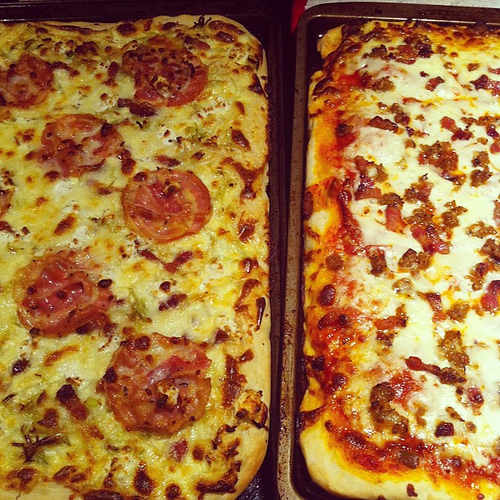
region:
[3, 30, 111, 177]
pizza with meat toppings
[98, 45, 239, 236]
pizza with meat toppings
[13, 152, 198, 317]
pizza with meat toppings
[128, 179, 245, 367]
pizza with meat toppings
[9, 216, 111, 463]
pizza with meat toppings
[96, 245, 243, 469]
pizza with meat toppings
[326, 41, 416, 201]
pizza with meat toppings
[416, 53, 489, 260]
pizza with meat toppings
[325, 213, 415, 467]
pizza with meat toppings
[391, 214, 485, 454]
pizza with meat toppings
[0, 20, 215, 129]
cheese and pepperoni on pizza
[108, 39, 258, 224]
cheese and pepperoni on pizza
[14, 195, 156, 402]
cheese and pepperoni on pizza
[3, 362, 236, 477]
cheese and pepperoni on pizza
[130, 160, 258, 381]
cheese and pepperoni on pizza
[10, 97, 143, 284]
cheese and pepperoni on pizza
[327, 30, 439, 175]
cheese and sausage on pizza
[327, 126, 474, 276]
cheese and sausage on pizza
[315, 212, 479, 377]
cheese and sausage on pizza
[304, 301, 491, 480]
cheese and sausage on pizza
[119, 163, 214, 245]
a piece of ham on the pizza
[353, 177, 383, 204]
a piece of sausage on the pizza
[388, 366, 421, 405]
a piece of bacon on the pizza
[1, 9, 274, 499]
a pizza with ham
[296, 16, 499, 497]
a pizza with sausage and bacon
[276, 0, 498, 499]
a metal pan under the pizza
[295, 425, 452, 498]
a brown crust on the pizza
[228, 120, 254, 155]
a brown spot on the pizza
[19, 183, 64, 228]
yellow cheese on the pizza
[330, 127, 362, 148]
a spot of tomato sauce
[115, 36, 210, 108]
Top middle pepperoni.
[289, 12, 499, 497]
Pizza on the right.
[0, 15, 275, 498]
A pepperoni pizza on the left.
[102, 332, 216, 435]
Bottom middle piece of pepperoni.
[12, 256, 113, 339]
Left piece of pepperoni on the bottom.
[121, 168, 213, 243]
A middle piece of pepperoni on the right.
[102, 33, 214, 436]
Three pieces of pepperoni coming down the inside edge.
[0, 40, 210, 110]
Top two pieces of pepperoni.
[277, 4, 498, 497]
Right side pan that a pizza is in.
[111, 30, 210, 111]
Top right piece of pepperoni.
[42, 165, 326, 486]
pizza is color yellow